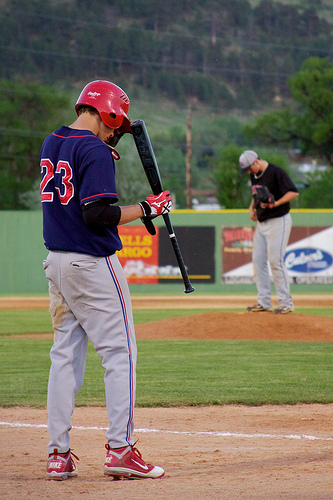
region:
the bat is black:
[121, 115, 201, 310]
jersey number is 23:
[28, 146, 79, 215]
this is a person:
[17, 89, 148, 494]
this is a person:
[226, 140, 307, 329]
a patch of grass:
[156, 341, 207, 383]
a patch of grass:
[196, 372, 245, 408]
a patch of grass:
[4, 343, 45, 390]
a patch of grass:
[263, 358, 322, 395]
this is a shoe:
[99, 435, 173, 484]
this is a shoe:
[40, 430, 93, 479]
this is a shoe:
[272, 294, 296, 321]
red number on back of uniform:
[30, 152, 104, 211]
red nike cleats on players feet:
[78, 439, 186, 491]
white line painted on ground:
[221, 425, 327, 451]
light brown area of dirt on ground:
[206, 466, 280, 494]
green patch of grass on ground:
[195, 348, 261, 397]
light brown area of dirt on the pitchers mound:
[212, 309, 286, 339]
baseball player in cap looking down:
[214, 138, 277, 174]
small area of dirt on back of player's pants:
[42, 297, 81, 335]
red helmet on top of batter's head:
[78, 65, 136, 127]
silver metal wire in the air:
[181, 60, 258, 88]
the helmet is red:
[75, 80, 132, 130]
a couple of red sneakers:
[47, 448, 164, 476]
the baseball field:
[163, 343, 332, 492]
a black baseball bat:
[132, 121, 195, 293]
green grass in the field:
[176, 353, 318, 394]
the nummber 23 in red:
[35, 159, 73, 205]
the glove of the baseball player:
[252, 185, 276, 210]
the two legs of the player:
[45, 262, 156, 477]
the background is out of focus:
[167, 7, 328, 127]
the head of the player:
[73, 79, 128, 139]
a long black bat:
[132, 119, 199, 295]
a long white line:
[135, 425, 331, 446]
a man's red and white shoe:
[103, 441, 165, 477]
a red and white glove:
[138, 190, 173, 218]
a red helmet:
[72, 78, 129, 131]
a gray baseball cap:
[233, 150, 261, 175]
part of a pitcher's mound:
[142, 310, 330, 344]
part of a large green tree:
[235, 55, 332, 152]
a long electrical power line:
[5, 36, 289, 82]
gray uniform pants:
[42, 247, 139, 453]